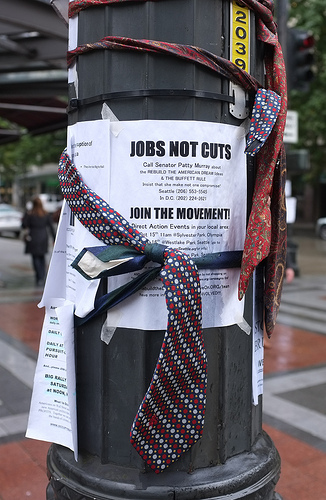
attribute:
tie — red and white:
[145, 261, 216, 456]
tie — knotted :
[121, 229, 156, 270]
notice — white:
[77, 123, 254, 343]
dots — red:
[152, 283, 236, 333]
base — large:
[43, 445, 279, 498]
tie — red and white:
[66, 176, 147, 258]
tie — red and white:
[56, 159, 218, 416]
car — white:
[0, 192, 39, 233]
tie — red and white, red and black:
[57, 146, 208, 474]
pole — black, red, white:
[45, 2, 282, 497]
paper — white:
[109, 117, 248, 330]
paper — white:
[22, 296, 78, 459]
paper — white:
[36, 119, 112, 315]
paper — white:
[250, 254, 263, 401]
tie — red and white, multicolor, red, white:
[56, 88, 283, 473]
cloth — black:
[66, 246, 240, 323]